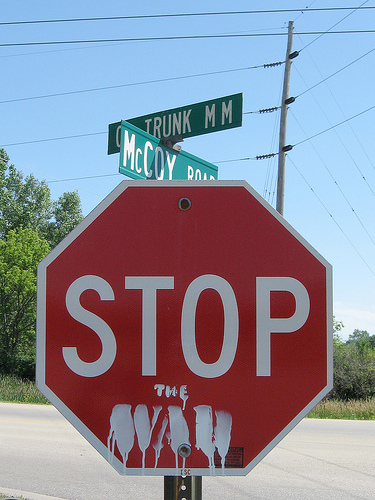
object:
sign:
[114, 120, 223, 188]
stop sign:
[30, 177, 337, 482]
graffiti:
[108, 381, 233, 473]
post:
[97, 380, 243, 482]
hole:
[177, 482, 189, 491]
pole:
[162, 474, 202, 498]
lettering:
[139, 99, 240, 138]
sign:
[105, 89, 246, 159]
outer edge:
[32, 174, 334, 479]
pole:
[277, 86, 290, 117]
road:
[0, 404, 370, 500]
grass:
[0, 369, 375, 418]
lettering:
[61, 271, 309, 380]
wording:
[101, 380, 240, 479]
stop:
[60, 268, 310, 386]